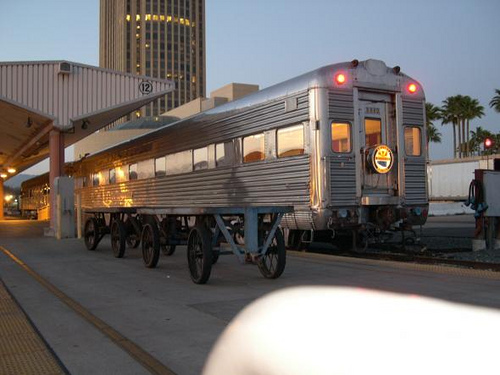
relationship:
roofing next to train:
[0, 59, 176, 234] [21, 59, 431, 252]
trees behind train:
[426, 88, 500, 162] [21, 59, 431, 252]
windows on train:
[23, 117, 422, 200] [21, 59, 431, 252]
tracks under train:
[282, 241, 499, 276] [21, 59, 431, 252]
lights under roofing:
[0, 163, 18, 179] [0, 59, 176, 234]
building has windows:
[100, 1, 207, 134] [99, 0, 205, 132]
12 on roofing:
[140, 82, 151, 93] [0, 59, 176, 234]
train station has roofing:
[1, 60, 500, 373] [0, 59, 176, 234]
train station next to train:
[1, 60, 500, 373] [21, 59, 431, 252]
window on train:
[330, 120, 353, 155] [21, 59, 431, 252]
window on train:
[276, 124, 305, 158] [21, 59, 431, 252]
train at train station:
[21, 59, 431, 252] [1, 60, 500, 373]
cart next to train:
[83, 206, 295, 285] [21, 59, 431, 252]